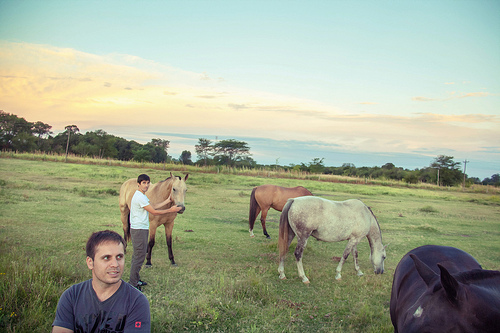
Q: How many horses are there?
A: Four.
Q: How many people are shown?
A: Two.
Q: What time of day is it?
A: Evening.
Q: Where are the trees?
A: In field.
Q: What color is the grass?
A: Green.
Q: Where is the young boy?
A: In grass.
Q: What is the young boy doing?
A: Touching horses.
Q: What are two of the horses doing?
A: Grazing.